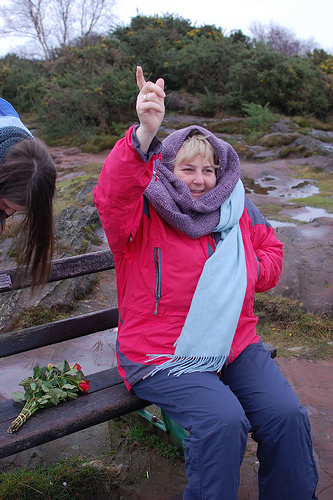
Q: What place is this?
A: It is a park.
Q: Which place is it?
A: It is a park.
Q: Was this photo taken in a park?
A: Yes, it was taken in a park.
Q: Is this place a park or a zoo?
A: It is a park.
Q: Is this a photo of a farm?
A: No, the picture is showing a park.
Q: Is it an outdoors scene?
A: Yes, it is outdoors.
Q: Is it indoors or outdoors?
A: It is outdoors.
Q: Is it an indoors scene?
A: No, it is outdoors.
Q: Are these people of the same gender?
A: Yes, all the people are female.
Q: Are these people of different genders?
A: No, all the people are female.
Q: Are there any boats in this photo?
A: No, there are no boats.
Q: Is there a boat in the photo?
A: No, there are no boats.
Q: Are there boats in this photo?
A: No, there are no boats.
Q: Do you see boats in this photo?
A: No, there are no boats.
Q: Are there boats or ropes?
A: No, there are no boats or ropes.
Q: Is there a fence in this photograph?
A: No, there are no fences.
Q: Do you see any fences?
A: No, there are no fences.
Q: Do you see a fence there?
A: No, there are no fences.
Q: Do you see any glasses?
A: No, there are no glasses.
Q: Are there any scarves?
A: Yes, there is a scarf.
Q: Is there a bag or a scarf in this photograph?
A: Yes, there is a scarf.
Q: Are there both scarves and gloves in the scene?
A: No, there is a scarf but no gloves.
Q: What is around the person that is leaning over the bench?
A: The scarf is around the girl.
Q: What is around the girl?
A: The scarf is around the girl.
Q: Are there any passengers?
A: No, there are no passengers.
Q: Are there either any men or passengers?
A: No, there are no passengers or men.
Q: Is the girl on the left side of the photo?
A: Yes, the girl is on the left of the image.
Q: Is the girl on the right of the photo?
A: No, the girl is on the left of the image.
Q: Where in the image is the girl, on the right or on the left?
A: The girl is on the left of the image.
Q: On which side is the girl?
A: The girl is on the left of the image.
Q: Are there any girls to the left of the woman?
A: Yes, there is a girl to the left of the woman.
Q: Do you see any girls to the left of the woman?
A: Yes, there is a girl to the left of the woman.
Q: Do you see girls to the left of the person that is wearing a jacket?
A: Yes, there is a girl to the left of the woman.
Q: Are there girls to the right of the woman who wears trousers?
A: No, the girl is to the left of the woman.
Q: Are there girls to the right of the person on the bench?
A: No, the girl is to the left of the woman.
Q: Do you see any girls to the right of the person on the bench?
A: No, the girl is to the left of the woman.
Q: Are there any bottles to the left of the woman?
A: No, there is a girl to the left of the woman.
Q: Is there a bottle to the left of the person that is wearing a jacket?
A: No, there is a girl to the left of the woman.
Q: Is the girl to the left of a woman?
A: Yes, the girl is to the left of a woman.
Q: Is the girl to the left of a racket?
A: No, the girl is to the left of a woman.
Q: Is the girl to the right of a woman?
A: No, the girl is to the left of a woman.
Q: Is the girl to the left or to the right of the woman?
A: The girl is to the left of the woman.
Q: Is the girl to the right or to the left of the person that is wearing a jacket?
A: The girl is to the left of the woman.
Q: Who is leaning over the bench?
A: The girl is leaning over the bench.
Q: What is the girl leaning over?
A: The girl is leaning over the bench.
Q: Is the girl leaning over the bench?
A: Yes, the girl is leaning over the bench.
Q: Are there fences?
A: No, there are no fences.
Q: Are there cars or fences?
A: No, there are no fences or cars.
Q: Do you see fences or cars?
A: No, there are no fences or cars.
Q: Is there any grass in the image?
A: Yes, there is grass.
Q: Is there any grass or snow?
A: Yes, there is grass.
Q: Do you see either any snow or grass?
A: Yes, there is grass.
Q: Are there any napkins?
A: No, there are no napkins.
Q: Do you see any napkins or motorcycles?
A: No, there are no napkins or motorcycles.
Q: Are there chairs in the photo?
A: No, there are no chairs.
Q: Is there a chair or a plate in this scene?
A: No, there are no chairs or plates.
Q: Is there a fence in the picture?
A: No, there are no fences.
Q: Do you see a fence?
A: No, there are no fences.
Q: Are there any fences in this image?
A: No, there are no fences.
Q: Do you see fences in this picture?
A: No, there are no fences.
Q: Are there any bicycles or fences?
A: No, there are no fences or bicycles.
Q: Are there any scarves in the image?
A: Yes, there is a scarf.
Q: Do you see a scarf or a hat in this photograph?
A: Yes, there is a scarf.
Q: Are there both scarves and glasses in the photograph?
A: No, there is a scarf but no glasses.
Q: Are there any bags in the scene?
A: No, there are no bags.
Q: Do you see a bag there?
A: No, there are no bags.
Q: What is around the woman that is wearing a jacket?
A: The scarf is around the woman.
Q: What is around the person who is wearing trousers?
A: The scarf is around the woman.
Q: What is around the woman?
A: The scarf is around the woman.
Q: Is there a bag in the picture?
A: No, there are no bags.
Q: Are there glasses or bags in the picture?
A: No, there are no bags or glasses.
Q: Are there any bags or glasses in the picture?
A: No, there are no bags or glasses.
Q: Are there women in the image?
A: Yes, there is a woman.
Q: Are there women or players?
A: Yes, there is a woman.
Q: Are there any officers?
A: No, there are no officers.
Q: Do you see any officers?
A: No, there are no officers.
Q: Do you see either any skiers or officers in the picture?
A: No, there are no officers or skiers.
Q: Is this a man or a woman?
A: This is a woman.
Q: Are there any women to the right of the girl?
A: Yes, there is a woman to the right of the girl.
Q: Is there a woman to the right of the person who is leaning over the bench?
A: Yes, there is a woman to the right of the girl.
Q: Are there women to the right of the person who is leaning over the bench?
A: Yes, there is a woman to the right of the girl.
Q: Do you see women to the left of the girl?
A: No, the woman is to the right of the girl.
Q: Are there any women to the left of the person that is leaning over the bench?
A: No, the woman is to the right of the girl.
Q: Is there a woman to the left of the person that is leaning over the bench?
A: No, the woman is to the right of the girl.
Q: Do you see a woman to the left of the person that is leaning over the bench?
A: No, the woman is to the right of the girl.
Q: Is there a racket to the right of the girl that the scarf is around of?
A: No, there is a woman to the right of the girl.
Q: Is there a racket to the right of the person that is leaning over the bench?
A: No, there is a woman to the right of the girl.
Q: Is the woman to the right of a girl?
A: Yes, the woman is to the right of a girl.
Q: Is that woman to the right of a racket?
A: No, the woman is to the right of a girl.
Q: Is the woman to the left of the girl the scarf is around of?
A: No, the woman is to the right of the girl.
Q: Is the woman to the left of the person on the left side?
A: No, the woman is to the right of the girl.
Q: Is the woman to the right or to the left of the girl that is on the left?
A: The woman is to the right of the girl.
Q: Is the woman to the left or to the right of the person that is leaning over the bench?
A: The woman is to the right of the girl.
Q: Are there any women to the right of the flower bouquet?
A: Yes, there is a woman to the right of the flower bouquet.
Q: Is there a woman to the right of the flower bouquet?
A: Yes, there is a woman to the right of the flower bouquet.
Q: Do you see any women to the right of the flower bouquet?
A: Yes, there is a woman to the right of the flower bouquet.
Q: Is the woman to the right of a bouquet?
A: Yes, the woman is to the right of a bouquet.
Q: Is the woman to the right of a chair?
A: No, the woman is to the right of a bouquet.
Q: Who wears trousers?
A: The woman wears trousers.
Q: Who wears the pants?
A: The woman wears trousers.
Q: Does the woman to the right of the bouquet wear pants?
A: Yes, the woman wears pants.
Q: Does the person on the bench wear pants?
A: Yes, the woman wears pants.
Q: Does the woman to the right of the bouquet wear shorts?
A: No, the woman wears pants.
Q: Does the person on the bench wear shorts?
A: No, the woman wears pants.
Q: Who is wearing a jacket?
A: The woman is wearing a jacket.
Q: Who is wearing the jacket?
A: The woman is wearing a jacket.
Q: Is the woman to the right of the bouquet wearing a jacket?
A: Yes, the woman is wearing a jacket.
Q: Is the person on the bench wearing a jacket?
A: Yes, the woman is wearing a jacket.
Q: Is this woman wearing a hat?
A: No, the woman is wearing a jacket.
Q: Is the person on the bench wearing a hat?
A: No, the woman is wearing a jacket.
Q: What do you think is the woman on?
A: The woman is on the bench.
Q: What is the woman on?
A: The woman is on the bench.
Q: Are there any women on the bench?
A: Yes, there is a woman on the bench.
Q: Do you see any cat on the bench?
A: No, there is a woman on the bench.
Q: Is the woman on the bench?
A: Yes, the woman is on the bench.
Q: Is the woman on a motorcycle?
A: No, the woman is on the bench.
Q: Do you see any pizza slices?
A: No, there are no pizza slices.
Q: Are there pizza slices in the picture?
A: No, there are no pizza slices.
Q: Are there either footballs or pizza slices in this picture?
A: No, there are no pizza slices or footballs.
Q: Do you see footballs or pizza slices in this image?
A: No, there are no pizza slices or footballs.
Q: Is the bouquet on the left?
A: Yes, the bouquet is on the left of the image.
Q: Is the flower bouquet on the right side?
A: No, the flower bouquet is on the left of the image.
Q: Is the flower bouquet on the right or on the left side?
A: The flower bouquet is on the left of the image.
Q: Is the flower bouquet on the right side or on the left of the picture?
A: The flower bouquet is on the left of the image.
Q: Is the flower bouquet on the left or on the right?
A: The flower bouquet is on the left of the image.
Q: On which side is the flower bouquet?
A: The flower bouquet is on the left of the image.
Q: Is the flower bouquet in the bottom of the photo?
A: Yes, the flower bouquet is in the bottom of the image.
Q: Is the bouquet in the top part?
A: No, the bouquet is in the bottom of the image.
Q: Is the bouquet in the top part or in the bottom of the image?
A: The bouquet is in the bottom of the image.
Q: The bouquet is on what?
A: The bouquet is on the bench.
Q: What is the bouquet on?
A: The bouquet is on the bench.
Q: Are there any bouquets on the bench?
A: Yes, there is a bouquet on the bench.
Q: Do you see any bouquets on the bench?
A: Yes, there is a bouquet on the bench.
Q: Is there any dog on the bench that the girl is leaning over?
A: No, there is a bouquet on the bench.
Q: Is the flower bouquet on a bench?
A: Yes, the flower bouquet is on a bench.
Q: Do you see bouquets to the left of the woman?
A: Yes, there is a bouquet to the left of the woman.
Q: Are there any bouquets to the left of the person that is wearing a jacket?
A: Yes, there is a bouquet to the left of the woman.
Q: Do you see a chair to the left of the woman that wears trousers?
A: No, there is a bouquet to the left of the woman.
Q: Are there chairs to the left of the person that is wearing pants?
A: No, there is a bouquet to the left of the woman.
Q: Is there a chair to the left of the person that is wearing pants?
A: No, there is a bouquet to the left of the woman.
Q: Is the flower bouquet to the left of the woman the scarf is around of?
A: Yes, the flower bouquet is to the left of the woman.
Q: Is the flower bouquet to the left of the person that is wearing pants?
A: Yes, the flower bouquet is to the left of the woman.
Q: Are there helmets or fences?
A: No, there are no fences or helmets.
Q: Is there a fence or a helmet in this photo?
A: No, there are no fences or helmets.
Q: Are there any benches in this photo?
A: Yes, there is a bench.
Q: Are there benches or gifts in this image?
A: Yes, there is a bench.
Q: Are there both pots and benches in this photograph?
A: No, there is a bench but no pots.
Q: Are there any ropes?
A: No, there are no ropes.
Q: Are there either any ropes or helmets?
A: No, there are no ropes or helmets.